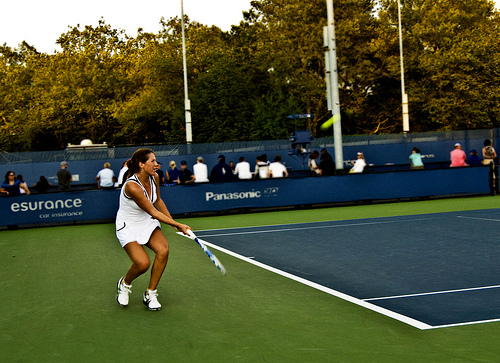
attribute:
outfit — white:
[115, 175, 172, 249]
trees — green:
[171, 51, 308, 151]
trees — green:
[233, 0, 393, 122]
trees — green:
[368, 0, 499, 128]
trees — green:
[113, 20, 218, 141]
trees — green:
[1, 40, 127, 142]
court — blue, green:
[216, 211, 477, 355]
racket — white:
[176, 220, 247, 289]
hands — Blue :
[145, 200, 209, 235]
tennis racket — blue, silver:
[180, 226, 229, 281]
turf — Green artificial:
[4, 206, 495, 361]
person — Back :
[448, 143, 463, 166]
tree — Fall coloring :
[20, 46, 97, 146]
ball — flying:
[322, 113, 341, 130]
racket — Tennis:
[149, 210, 251, 262]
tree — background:
[132, 3, 277, 162]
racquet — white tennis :
[173, 217, 227, 277]